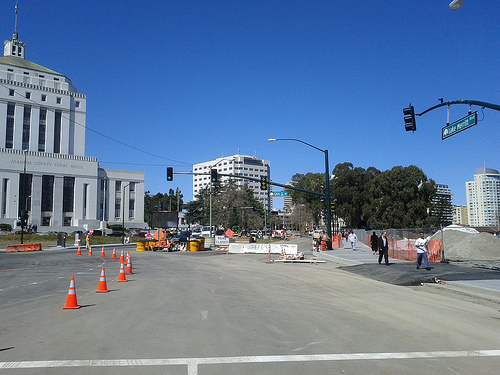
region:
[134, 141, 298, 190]
green traffic lights over roadway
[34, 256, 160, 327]
orange and white cones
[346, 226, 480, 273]
people walking on sidewalk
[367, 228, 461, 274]
orange construction net by sidewalk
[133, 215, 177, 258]
orange and black sign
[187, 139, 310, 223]
white building with windows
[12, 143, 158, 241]
concrete building with tall windows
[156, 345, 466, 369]
white line painted on roadway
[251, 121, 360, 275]
streetlight near traffic signal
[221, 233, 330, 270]
white barrier in roadway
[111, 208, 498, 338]
Road Construction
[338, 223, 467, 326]
Men walking on the sidewalk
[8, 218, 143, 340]
Crossing Guard signaling traffic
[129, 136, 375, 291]
Traffic signals are green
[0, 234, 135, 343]
Orange cones to replace lane markings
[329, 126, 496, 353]
Fence in place to avoid others from going into a dangerious work zone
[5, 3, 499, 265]
A whole bunch of tall buildings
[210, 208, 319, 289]
a barrier to help stop traffic from going into the construction site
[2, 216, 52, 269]
A barrier to assist with keeping vehicles from going into a construction zone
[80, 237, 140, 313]
Orange traffic cones.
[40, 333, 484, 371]
White markings on street.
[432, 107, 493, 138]
Street sign under traffic light.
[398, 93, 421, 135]
Traffic light.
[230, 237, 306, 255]
White traffic barrier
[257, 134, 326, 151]
City street light.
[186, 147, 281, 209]
White high-rise building.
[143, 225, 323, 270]
Street under Construction or repair.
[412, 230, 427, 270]
Man in white shirt and jean walking.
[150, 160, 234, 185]
Two traffic lights showing green.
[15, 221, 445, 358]
a road construction detour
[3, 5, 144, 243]
an important building is roadside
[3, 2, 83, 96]
the building has a flagpole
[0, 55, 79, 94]
a white fence is on the building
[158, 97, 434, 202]
traffic signals are above the street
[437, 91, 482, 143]
a directional sign is on a pole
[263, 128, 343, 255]
a street light is over the street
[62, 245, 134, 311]
orange and white cones are on the street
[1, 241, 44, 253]
an orange barrier is on the street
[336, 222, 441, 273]
people are walking on the sidewalk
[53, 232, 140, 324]
a few orange traffic cones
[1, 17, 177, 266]
a large white courthouse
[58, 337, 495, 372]
a white line in the street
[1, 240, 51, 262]
a dirty orange barrier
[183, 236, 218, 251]
large yellow buckets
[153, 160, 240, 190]
a pair of traffic lights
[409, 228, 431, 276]
a man in jeans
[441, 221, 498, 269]
a pile of gravel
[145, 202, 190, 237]
a large construction sign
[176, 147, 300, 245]
a tall white office building